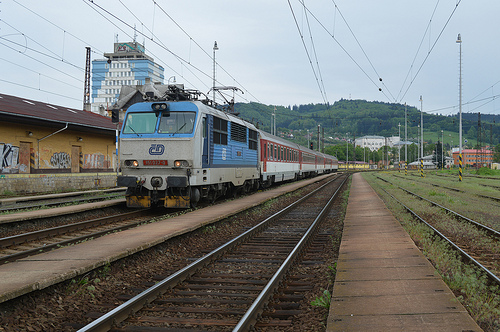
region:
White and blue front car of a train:
[125, 102, 203, 189]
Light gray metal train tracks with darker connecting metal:
[218, 207, 308, 312]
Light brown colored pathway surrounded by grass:
[346, 195, 431, 329]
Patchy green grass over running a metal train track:
[394, 178, 463, 238]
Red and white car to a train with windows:
[255, 132, 300, 175]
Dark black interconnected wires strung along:
[293, 12, 438, 108]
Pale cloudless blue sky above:
[216, 8, 295, 93]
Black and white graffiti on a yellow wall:
[42, 147, 78, 169]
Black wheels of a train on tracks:
[180, 187, 223, 204]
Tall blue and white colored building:
[93, 37, 156, 86]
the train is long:
[106, 86, 387, 218]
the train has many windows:
[262, 132, 341, 172]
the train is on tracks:
[0, 164, 386, 330]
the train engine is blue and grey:
[110, 85, 262, 197]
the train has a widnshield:
[116, 105, 205, 146]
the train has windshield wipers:
[126, 121, 191, 143]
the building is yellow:
[0, 92, 128, 206]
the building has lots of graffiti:
[0, 94, 125, 171]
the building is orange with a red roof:
[446, 143, 496, 173]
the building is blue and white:
[80, 51, 177, 127]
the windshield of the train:
[121, 105, 199, 137]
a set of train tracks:
[67, 162, 359, 330]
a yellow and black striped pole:
[451, 150, 465, 182]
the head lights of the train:
[171, 154, 191, 170]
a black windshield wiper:
[166, 118, 189, 138]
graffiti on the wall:
[44, 146, 75, 169]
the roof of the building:
[0, 90, 128, 135]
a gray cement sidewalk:
[0, 165, 341, 302]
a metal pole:
[76, 42, 96, 114]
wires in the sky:
[283, 0, 343, 115]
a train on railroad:
[100, 87, 351, 209]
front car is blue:
[110, 90, 265, 197]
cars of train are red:
[256, 127, 351, 174]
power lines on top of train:
[5, 5, 475, 97]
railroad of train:
[12, 200, 497, 318]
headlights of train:
[118, 152, 195, 176]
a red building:
[444, 141, 493, 175]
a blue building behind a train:
[76, 32, 173, 118]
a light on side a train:
[206, 34, 226, 100]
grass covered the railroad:
[356, 157, 498, 299]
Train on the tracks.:
[112, 93, 342, 213]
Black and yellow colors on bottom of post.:
[456, 152, 464, 179]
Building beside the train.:
[1, 93, 117, 175]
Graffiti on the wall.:
[0, 138, 27, 173]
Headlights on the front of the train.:
[126, 156, 184, 170]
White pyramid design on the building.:
[92, 59, 137, 119]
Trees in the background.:
[231, 93, 498, 140]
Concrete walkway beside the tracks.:
[329, 160, 479, 329]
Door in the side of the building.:
[66, 140, 86, 177]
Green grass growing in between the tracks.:
[363, 168, 498, 325]